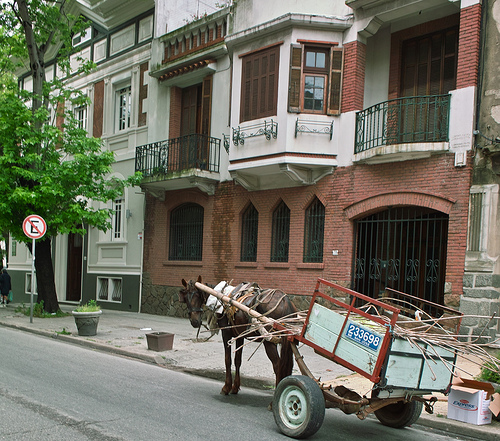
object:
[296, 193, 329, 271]
window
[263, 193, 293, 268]
window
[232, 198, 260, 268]
window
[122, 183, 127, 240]
frame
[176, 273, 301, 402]
brown horse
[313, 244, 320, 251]
window coverings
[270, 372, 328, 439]
black tire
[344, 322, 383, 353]
license plate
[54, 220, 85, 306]
door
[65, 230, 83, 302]
insert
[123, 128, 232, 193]
balcony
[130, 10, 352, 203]
second floor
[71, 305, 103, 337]
flower pot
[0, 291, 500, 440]
city street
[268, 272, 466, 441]
cart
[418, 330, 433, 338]
tree limbs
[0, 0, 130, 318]
tree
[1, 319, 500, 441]
city sidewalk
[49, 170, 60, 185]
leaves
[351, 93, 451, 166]
balcony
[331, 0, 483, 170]
second floor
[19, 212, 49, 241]
directional sign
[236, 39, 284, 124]
windows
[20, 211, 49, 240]
street sign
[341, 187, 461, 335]
iron gate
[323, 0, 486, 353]
building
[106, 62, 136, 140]
window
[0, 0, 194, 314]
building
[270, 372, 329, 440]
wheel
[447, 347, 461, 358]
sticks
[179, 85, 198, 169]
screen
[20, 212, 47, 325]
sign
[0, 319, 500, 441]
curb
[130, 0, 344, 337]
building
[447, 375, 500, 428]
box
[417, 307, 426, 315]
sticks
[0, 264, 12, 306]
person